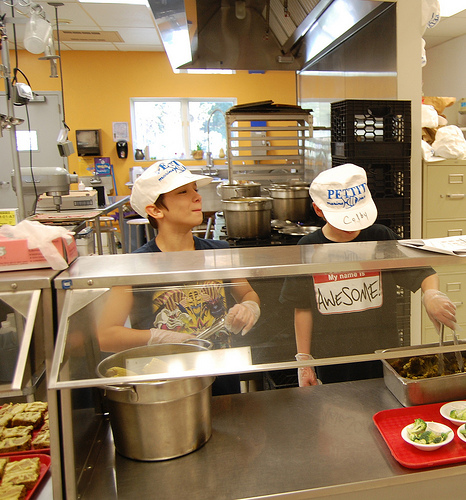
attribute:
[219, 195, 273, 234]
pot — cooking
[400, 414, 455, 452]
bowl — white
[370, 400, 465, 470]
cafeteria tray — red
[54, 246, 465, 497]
case — display, metal, food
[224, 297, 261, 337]
glove — clear, sanitary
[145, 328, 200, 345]
glove — clear, sanitary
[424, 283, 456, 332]
glove — clear, sanitary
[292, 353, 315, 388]
glove — clear, sanitary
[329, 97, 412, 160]
milk container — brown, plastic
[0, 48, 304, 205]
wall — yellow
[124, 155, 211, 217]
cap — white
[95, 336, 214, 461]
pot — stainless steel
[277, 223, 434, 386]
t-shirt — black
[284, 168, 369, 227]
cap — white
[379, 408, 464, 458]
tray — red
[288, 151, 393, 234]
cap — white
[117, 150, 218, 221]
cap — white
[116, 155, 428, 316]
kids — both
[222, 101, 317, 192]
tray cart — metal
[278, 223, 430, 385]
top — black